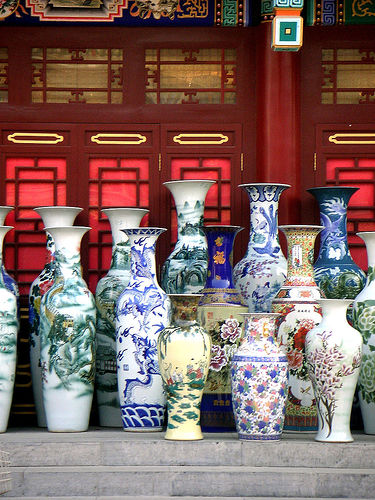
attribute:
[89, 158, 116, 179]
section — red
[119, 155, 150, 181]
section — red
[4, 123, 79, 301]
door — red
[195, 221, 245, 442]
blue vase — chinese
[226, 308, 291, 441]
vase — blue, pink, floral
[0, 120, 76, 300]
door — red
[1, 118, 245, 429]
door — red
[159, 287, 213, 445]
vase — blue and white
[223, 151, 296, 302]
vase — blue, white, chinese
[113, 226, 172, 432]
vase — blue, white, chinese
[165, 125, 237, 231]
door — red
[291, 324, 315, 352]
flower — green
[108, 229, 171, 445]
vase — Blue , white 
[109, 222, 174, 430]
vase — white , Blue , flowered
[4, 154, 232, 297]
windows — red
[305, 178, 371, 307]
vase — blue, white, green, chinese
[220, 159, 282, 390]
vase — blue and white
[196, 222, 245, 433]
vase — blue, tan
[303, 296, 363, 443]
vase — white , Chinese , pink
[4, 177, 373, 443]
vases — traditional, art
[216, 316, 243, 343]
flower — white, pink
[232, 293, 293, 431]
vase — Blue, white 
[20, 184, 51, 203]
section/door — red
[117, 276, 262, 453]
vase — white, blue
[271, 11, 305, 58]
socket — white, green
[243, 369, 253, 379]
flower — blue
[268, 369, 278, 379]
flower — blue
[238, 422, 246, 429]
flower — blue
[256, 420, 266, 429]
flower — blue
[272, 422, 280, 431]
flower — blue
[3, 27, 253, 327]
door — red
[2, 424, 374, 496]
surface — gray